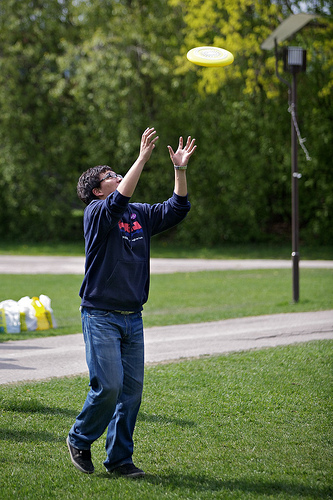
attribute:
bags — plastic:
[2, 289, 61, 333]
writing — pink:
[115, 218, 144, 230]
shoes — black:
[44, 407, 190, 489]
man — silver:
[84, 136, 250, 295]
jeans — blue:
[66, 305, 144, 465]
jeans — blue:
[60, 293, 156, 455]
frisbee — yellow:
[184, 45, 234, 68]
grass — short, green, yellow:
[143, 342, 330, 494]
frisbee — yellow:
[175, 35, 245, 75]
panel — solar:
[257, 13, 315, 53]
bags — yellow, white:
[4, 293, 58, 338]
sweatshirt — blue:
[80, 190, 192, 311]